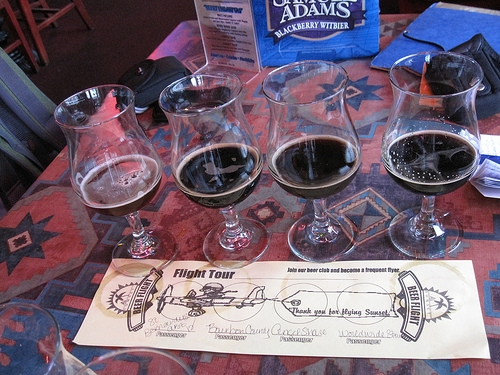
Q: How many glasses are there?
A: Four.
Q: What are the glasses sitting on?
A: A table.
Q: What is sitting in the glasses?
A: Liquid.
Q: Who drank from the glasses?
A: Men and women.